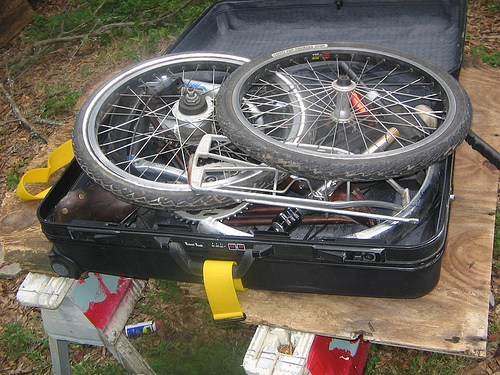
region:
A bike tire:
[217, 41, 472, 180]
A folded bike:
[51, 38, 497, 243]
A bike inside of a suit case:
[15, 0, 498, 328]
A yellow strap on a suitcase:
[202, 259, 250, 326]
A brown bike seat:
[53, 183, 135, 224]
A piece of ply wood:
[0, 53, 499, 360]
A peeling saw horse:
[16, 270, 160, 374]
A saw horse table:
[3, 52, 496, 372]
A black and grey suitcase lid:
[159, 0, 466, 78]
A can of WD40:
[124, 318, 163, 337]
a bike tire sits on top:
[216, 43, 468, 170]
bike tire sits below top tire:
[75, 54, 294, 202]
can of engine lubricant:
[129, 320, 164, 336]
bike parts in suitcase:
[171, 191, 381, 238]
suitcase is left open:
[61, 0, 471, 285]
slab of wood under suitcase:
[449, 50, 497, 356]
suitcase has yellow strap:
[206, 260, 239, 327]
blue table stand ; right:
[38, 273, 151, 369]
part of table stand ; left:
[243, 330, 368, 365]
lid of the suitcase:
[190, 2, 473, 43]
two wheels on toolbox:
[55, 41, 466, 221]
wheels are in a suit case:
[64, 37, 473, 212]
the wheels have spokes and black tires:
[71, 42, 473, 211]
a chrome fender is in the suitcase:
[334, 124, 444, 246]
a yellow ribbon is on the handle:
[199, 254, 249, 326]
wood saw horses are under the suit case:
[12, 267, 381, 374]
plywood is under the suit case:
[17, 57, 489, 362]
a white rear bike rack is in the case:
[187, 128, 410, 213]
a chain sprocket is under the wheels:
[165, 166, 252, 225]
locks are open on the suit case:
[58, 221, 390, 273]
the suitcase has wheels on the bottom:
[43, 243, 84, 283]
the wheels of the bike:
[69, 38, 466, 210]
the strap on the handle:
[203, 257, 251, 329]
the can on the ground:
[123, 320, 167, 342]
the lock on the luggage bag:
[194, 236, 246, 254]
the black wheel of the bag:
[44, 248, 82, 285]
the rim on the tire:
[269, 62, 415, 141]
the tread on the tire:
[271, 153, 421, 184]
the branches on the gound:
[1, 18, 78, 137]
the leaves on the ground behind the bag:
[468, 0, 495, 59]